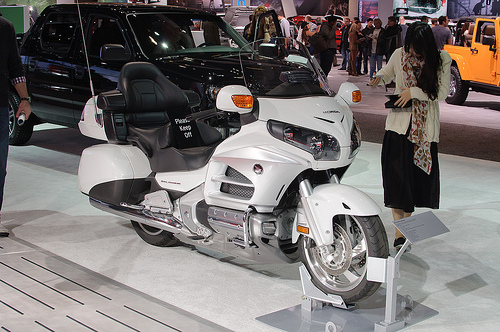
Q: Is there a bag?
A: No, there are no bags.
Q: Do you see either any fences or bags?
A: No, there are no bags or fences.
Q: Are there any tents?
A: No, there are no tents.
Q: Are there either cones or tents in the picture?
A: No, there are no tents or cones.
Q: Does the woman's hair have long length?
A: Yes, the hair is long.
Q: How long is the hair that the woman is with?
A: The hair is long.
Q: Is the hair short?
A: No, the hair is long.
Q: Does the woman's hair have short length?
A: No, the hair is long.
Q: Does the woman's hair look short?
A: No, the hair is long.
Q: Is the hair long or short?
A: The hair is long.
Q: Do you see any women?
A: Yes, there is a woman.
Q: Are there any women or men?
A: Yes, there is a woman.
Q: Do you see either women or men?
A: Yes, there is a woman.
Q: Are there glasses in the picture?
A: No, there are no glasses.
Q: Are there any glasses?
A: No, there are no glasses.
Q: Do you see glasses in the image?
A: No, there are no glasses.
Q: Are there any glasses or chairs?
A: No, there are no glasses or chairs.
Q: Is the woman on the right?
A: Yes, the woman is on the right of the image.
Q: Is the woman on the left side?
A: No, the woman is on the right of the image.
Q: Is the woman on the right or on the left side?
A: The woman is on the right of the image.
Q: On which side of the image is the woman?
A: The woman is on the right of the image.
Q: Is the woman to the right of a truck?
A: Yes, the woman is to the right of a truck.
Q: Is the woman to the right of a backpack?
A: No, the woman is to the right of a truck.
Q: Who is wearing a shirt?
A: The woman is wearing a shirt.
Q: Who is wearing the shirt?
A: The woman is wearing a shirt.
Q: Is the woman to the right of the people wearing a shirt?
A: Yes, the woman is wearing a shirt.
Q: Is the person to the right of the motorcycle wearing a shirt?
A: Yes, the woman is wearing a shirt.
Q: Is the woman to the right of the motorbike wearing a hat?
A: No, the woman is wearing a shirt.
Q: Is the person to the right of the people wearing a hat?
A: No, the woman is wearing a shirt.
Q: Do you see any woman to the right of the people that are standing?
A: Yes, there is a woman to the right of the people.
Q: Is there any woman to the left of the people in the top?
A: No, the woman is to the right of the people.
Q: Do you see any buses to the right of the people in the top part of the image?
A: No, there is a woman to the right of the people.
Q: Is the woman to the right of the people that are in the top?
A: Yes, the woman is to the right of the people.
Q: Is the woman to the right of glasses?
A: No, the woman is to the right of the people.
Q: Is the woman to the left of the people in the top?
A: No, the woman is to the right of the people.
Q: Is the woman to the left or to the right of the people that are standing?
A: The woman is to the right of the people.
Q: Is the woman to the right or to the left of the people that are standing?
A: The woman is to the right of the people.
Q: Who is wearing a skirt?
A: The woman is wearing a skirt.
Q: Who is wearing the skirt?
A: The woman is wearing a skirt.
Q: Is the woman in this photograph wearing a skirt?
A: Yes, the woman is wearing a skirt.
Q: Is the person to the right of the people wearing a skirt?
A: Yes, the woman is wearing a skirt.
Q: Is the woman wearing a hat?
A: No, the woman is wearing a skirt.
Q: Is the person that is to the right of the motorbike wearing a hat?
A: No, the woman is wearing a skirt.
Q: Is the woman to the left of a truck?
A: Yes, the woman is to the left of a truck.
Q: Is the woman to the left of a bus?
A: No, the woman is to the left of a truck.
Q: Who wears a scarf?
A: The woman wears a scarf.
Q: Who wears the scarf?
A: The woman wears a scarf.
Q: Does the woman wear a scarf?
A: Yes, the woman wears a scarf.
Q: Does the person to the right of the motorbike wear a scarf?
A: Yes, the woman wears a scarf.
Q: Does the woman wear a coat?
A: No, the woman wears a scarf.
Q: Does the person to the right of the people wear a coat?
A: No, the woman wears a scarf.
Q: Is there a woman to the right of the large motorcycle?
A: Yes, there is a woman to the right of the motorbike.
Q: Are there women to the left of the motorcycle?
A: No, the woman is to the right of the motorcycle.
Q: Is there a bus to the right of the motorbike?
A: No, there is a woman to the right of the motorbike.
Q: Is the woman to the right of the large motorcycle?
A: Yes, the woman is to the right of the motorbike.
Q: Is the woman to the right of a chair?
A: No, the woman is to the right of the motorbike.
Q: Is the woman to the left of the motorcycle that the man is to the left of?
A: No, the woman is to the right of the motorbike.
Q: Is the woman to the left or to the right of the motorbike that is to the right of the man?
A: The woman is to the right of the motorcycle.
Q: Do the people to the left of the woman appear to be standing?
A: Yes, the people are standing.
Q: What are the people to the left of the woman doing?
A: The people are standing.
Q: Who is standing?
A: The people are standing.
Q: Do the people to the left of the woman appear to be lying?
A: No, the people are standing.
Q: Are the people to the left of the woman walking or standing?
A: The people are standing.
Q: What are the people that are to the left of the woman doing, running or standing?
A: The people are standing.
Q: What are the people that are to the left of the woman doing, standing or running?
A: The people are standing.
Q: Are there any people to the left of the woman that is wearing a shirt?
A: Yes, there are people to the left of the woman.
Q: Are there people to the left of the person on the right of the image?
A: Yes, there are people to the left of the woman.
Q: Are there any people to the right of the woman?
A: No, the people are to the left of the woman.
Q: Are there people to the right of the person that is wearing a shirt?
A: No, the people are to the left of the woman.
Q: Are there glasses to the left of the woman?
A: No, there are people to the left of the woman.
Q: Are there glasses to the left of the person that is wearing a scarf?
A: No, there are people to the left of the woman.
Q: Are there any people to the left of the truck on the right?
A: Yes, there are people to the left of the truck.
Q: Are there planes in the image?
A: No, there are no planes.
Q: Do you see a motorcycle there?
A: Yes, there is a motorcycle.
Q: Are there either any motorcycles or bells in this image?
A: Yes, there is a motorcycle.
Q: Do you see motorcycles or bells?
A: Yes, there is a motorcycle.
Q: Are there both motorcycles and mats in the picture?
A: No, there is a motorcycle but no mats.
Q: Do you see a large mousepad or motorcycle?
A: Yes, there is a large motorcycle.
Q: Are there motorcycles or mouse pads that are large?
A: Yes, the motorcycle is large.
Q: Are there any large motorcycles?
A: Yes, there is a large motorcycle.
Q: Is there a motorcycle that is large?
A: Yes, there is a motorcycle that is large.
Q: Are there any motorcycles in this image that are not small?
A: Yes, there is a large motorcycle.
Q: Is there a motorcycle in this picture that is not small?
A: Yes, there is a large motorcycle.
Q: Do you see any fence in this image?
A: No, there are no fences.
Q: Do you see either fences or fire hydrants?
A: No, there are no fences or fire hydrants.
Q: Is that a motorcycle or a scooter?
A: That is a motorcycle.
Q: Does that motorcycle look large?
A: Yes, the motorcycle is large.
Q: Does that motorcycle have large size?
A: Yes, the motorcycle is large.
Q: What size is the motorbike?
A: The motorbike is large.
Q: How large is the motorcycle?
A: The motorcycle is large.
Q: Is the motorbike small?
A: No, the motorbike is large.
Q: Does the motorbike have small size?
A: No, the motorbike is large.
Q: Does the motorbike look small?
A: No, the motorbike is large.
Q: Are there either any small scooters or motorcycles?
A: No, there is a motorcycle but it is large.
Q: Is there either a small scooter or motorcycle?
A: No, there is a motorcycle but it is large.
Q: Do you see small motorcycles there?
A: No, there is a motorcycle but it is large.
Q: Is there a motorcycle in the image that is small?
A: No, there is a motorcycle but it is large.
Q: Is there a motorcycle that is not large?
A: No, there is a motorcycle but it is large.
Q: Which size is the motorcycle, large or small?
A: The motorcycle is large.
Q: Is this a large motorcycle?
A: Yes, this is a large motorcycle.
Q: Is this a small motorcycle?
A: No, this is a large motorcycle.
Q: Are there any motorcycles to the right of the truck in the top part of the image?
A: No, the motorcycle is to the left of the truck.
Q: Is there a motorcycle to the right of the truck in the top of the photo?
A: No, the motorcycle is to the left of the truck.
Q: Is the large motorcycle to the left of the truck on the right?
A: Yes, the motorbike is to the left of the truck.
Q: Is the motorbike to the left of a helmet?
A: No, the motorbike is to the left of the truck.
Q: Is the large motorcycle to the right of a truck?
A: No, the motorbike is to the left of a truck.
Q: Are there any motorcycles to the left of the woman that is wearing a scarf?
A: Yes, there is a motorcycle to the left of the woman.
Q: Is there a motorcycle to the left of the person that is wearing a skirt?
A: Yes, there is a motorcycle to the left of the woman.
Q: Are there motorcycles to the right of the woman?
A: No, the motorcycle is to the left of the woman.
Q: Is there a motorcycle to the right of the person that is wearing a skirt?
A: No, the motorcycle is to the left of the woman.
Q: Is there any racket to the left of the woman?
A: No, there is a motorcycle to the left of the woman.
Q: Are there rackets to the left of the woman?
A: No, there is a motorcycle to the left of the woman.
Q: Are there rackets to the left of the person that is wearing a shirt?
A: No, there is a motorcycle to the left of the woman.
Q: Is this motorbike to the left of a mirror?
A: No, the motorbike is to the left of a woman.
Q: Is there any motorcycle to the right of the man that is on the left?
A: Yes, there is a motorcycle to the right of the man.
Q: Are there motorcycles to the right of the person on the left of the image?
A: Yes, there is a motorcycle to the right of the man.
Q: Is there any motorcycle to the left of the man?
A: No, the motorcycle is to the right of the man.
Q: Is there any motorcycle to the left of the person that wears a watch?
A: No, the motorcycle is to the right of the man.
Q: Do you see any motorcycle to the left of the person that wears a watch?
A: No, the motorcycle is to the right of the man.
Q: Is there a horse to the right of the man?
A: No, there is a motorcycle to the right of the man.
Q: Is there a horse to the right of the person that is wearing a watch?
A: No, there is a motorcycle to the right of the man.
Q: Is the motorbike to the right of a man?
A: Yes, the motorbike is to the right of a man.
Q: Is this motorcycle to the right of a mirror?
A: No, the motorcycle is to the right of a man.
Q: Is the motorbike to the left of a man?
A: No, the motorbike is to the right of a man.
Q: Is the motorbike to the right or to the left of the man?
A: The motorbike is to the right of the man.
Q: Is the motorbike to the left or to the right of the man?
A: The motorbike is to the right of the man.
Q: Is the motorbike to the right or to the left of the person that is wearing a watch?
A: The motorbike is to the right of the man.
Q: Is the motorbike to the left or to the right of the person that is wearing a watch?
A: The motorbike is to the right of the man.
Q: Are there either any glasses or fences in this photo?
A: No, there are no glasses or fences.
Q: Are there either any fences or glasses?
A: No, there are no glasses or fences.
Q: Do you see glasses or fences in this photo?
A: No, there are no glasses or fences.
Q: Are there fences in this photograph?
A: No, there are no fences.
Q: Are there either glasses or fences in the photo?
A: No, there are no fences or glasses.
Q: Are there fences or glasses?
A: No, there are no fences or glasses.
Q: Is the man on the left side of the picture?
A: Yes, the man is on the left of the image.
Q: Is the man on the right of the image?
A: No, the man is on the left of the image.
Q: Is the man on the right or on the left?
A: The man is on the left of the image.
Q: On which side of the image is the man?
A: The man is on the left of the image.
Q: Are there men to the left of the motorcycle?
A: Yes, there is a man to the left of the motorcycle.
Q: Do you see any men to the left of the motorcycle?
A: Yes, there is a man to the left of the motorcycle.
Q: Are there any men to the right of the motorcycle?
A: No, the man is to the left of the motorcycle.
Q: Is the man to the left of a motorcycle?
A: Yes, the man is to the left of a motorcycle.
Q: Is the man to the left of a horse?
A: No, the man is to the left of a motorcycle.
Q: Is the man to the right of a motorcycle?
A: No, the man is to the left of a motorcycle.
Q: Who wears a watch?
A: The man wears a watch.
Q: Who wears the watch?
A: The man wears a watch.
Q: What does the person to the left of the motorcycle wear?
A: The man wears a watch.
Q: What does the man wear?
A: The man wears a watch.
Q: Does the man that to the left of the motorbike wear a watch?
A: Yes, the man wears a watch.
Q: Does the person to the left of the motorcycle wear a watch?
A: Yes, the man wears a watch.